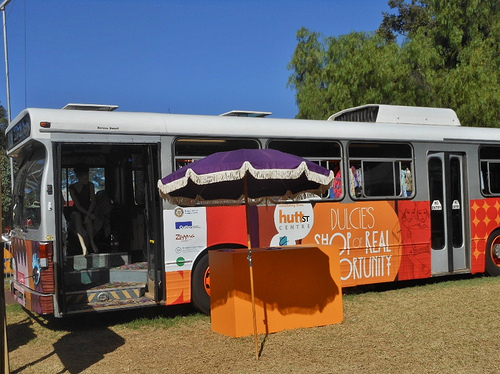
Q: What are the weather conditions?
A: It is clear.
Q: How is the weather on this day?
A: It is clear.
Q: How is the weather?
A: It is clear.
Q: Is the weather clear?
A: Yes, it is clear.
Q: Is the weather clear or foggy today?
A: It is clear.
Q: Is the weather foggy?
A: No, it is clear.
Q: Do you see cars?
A: No, there are no cars.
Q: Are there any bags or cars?
A: No, there are no cars or bags.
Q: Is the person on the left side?
A: Yes, the person is on the left of the image.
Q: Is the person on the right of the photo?
A: No, the person is on the left of the image.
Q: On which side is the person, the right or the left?
A: The person is on the left of the image.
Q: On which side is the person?
A: The person is on the left of the image.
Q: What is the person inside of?
A: The person is inside the bus.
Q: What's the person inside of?
A: The person is inside the bus.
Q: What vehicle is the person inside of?
A: The person is inside the bus.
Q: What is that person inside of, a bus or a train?
A: The person is inside a bus.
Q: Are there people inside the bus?
A: Yes, there is a person inside the bus.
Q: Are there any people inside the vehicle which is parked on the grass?
A: Yes, there is a person inside the bus.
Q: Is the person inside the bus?
A: Yes, the person is inside the bus.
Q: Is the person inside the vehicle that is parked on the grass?
A: Yes, the person is inside the bus.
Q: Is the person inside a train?
A: No, the person is inside the bus.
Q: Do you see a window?
A: Yes, there is a window.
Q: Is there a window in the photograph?
A: Yes, there is a window.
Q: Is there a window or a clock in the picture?
A: Yes, there is a window.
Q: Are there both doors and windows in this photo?
A: Yes, there are both a window and a door.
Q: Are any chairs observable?
A: No, there are no chairs.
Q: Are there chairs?
A: No, there are no chairs.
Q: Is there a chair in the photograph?
A: No, there are no chairs.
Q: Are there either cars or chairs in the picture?
A: No, there are no chairs or cars.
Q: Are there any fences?
A: No, there are no fences.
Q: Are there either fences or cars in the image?
A: No, there are no fences or cars.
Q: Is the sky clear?
A: Yes, the sky is clear.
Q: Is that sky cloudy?
A: No, the sky is clear.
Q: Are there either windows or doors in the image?
A: Yes, there is a window.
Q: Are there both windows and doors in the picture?
A: Yes, there are both a window and doors.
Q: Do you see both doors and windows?
A: Yes, there are both a window and doors.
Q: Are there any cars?
A: No, there are no cars.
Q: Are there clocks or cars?
A: No, there are no cars or clocks.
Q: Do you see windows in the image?
A: Yes, there is a window.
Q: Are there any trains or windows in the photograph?
A: Yes, there is a window.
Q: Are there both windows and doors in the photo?
A: Yes, there are both a window and a door.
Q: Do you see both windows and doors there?
A: Yes, there are both a window and a door.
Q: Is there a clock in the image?
A: No, there are no clocks.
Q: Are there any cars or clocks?
A: No, there are no clocks or cars.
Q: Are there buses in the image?
A: Yes, there is a bus.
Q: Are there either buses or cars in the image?
A: Yes, there is a bus.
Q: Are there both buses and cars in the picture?
A: No, there is a bus but no cars.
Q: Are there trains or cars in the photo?
A: No, there are no cars or trains.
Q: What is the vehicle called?
A: The vehicle is a bus.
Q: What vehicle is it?
A: The vehicle is a bus.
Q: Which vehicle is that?
A: This is a bus.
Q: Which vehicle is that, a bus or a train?
A: This is a bus.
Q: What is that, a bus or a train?
A: That is a bus.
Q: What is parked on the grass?
A: The bus is parked on the grass.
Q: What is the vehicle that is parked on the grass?
A: The vehicle is a bus.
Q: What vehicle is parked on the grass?
A: The vehicle is a bus.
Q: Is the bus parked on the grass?
A: Yes, the bus is parked on the grass.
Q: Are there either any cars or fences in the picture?
A: No, there are no cars or fences.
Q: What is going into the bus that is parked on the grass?
A: The step is going into the bus.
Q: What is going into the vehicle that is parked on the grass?
A: The step is going into the bus.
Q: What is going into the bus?
A: The step is going into the bus.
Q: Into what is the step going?
A: The step is going into the bus.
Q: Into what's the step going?
A: The step is going into the bus.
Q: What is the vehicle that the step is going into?
A: The vehicle is a bus.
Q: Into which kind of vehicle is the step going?
A: The step is going into the bus.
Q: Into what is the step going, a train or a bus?
A: The step is going into a bus.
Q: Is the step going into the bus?
A: Yes, the step is going into the bus.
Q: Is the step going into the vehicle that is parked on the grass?
A: Yes, the step is going into the bus.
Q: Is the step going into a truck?
A: No, the step is going into the bus.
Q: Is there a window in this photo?
A: Yes, there is a window.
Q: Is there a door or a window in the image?
A: Yes, there is a window.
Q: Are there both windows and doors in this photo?
A: Yes, there are both a window and a door.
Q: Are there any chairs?
A: No, there are no chairs.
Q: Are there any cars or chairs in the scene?
A: No, there are no chairs or cars.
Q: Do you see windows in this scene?
A: Yes, there is a window.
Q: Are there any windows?
A: Yes, there is a window.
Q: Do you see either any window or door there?
A: Yes, there is a window.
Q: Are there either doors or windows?
A: Yes, there is a window.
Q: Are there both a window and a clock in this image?
A: No, there is a window but no clocks.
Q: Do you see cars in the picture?
A: No, there are no cars.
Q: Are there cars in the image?
A: No, there are no cars.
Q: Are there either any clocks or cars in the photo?
A: No, there are no cars or clocks.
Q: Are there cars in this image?
A: No, there are no cars.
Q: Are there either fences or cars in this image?
A: No, there are no cars or fences.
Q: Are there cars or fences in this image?
A: No, there are no cars or fences.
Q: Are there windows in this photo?
A: Yes, there is a window.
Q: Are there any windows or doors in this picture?
A: Yes, there is a window.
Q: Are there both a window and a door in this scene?
A: Yes, there are both a window and a door.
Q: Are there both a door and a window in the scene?
A: Yes, there are both a window and a door.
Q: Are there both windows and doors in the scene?
A: Yes, there are both a window and doors.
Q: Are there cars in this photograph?
A: No, there are no cars.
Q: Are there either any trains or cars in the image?
A: No, there are no cars or trains.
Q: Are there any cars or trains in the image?
A: No, there are no cars or trains.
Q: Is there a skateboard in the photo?
A: No, there are no skateboards.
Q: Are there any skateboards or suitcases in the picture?
A: No, there are no skateboards or suitcases.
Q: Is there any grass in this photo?
A: Yes, there is grass.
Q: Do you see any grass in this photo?
A: Yes, there is grass.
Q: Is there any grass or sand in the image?
A: Yes, there is grass.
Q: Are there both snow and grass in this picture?
A: No, there is grass but no snow.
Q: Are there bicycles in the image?
A: No, there are no bicycles.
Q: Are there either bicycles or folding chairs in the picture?
A: No, there are no bicycles or folding chairs.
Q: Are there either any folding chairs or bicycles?
A: No, there are no bicycles or folding chairs.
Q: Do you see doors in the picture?
A: Yes, there is a door.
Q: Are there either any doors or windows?
A: Yes, there is a door.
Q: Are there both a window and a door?
A: Yes, there are both a door and a window.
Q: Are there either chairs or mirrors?
A: No, there are no chairs or mirrors.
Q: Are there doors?
A: Yes, there is a door.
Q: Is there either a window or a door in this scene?
A: Yes, there is a door.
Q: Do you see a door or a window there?
A: Yes, there is a door.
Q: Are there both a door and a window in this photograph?
A: Yes, there are both a door and a window.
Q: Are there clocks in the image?
A: No, there are no clocks.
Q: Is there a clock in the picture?
A: No, there are no clocks.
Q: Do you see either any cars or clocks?
A: No, there are no clocks or cars.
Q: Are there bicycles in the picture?
A: No, there are no bicycles.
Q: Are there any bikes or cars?
A: No, there are no bikes or cars.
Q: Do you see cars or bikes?
A: No, there are no bikes or cars.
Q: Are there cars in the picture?
A: No, there are no cars.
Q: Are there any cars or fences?
A: No, there are no cars or fences.